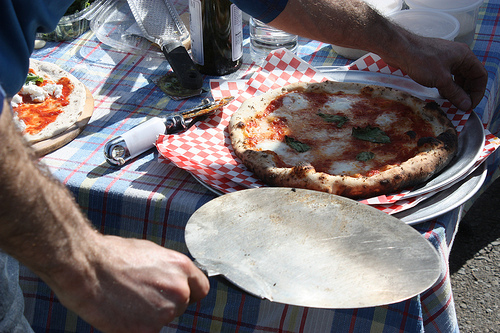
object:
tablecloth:
[6, 2, 495, 331]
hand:
[52, 232, 214, 331]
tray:
[182, 184, 445, 309]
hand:
[403, 34, 490, 112]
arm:
[0, 112, 99, 273]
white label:
[231, 4, 243, 60]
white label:
[190, 0, 202, 62]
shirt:
[1, 2, 286, 127]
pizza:
[10, 57, 88, 154]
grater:
[125, 0, 201, 91]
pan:
[180, 186, 441, 313]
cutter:
[102, 95, 234, 167]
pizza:
[228, 80, 457, 194]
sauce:
[258, 97, 432, 175]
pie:
[223, 78, 454, 195]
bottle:
[192, 1, 243, 76]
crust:
[228, 79, 456, 194]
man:
[0, 0, 491, 333]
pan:
[223, 76, 459, 191]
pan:
[381, 157, 486, 222]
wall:
[437, 230, 500, 333]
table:
[28, 3, 500, 276]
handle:
[102, 114, 171, 166]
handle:
[192, 261, 215, 275]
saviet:
[155, 46, 320, 189]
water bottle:
[247, 16, 298, 66]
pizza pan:
[179, 69, 486, 199]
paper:
[152, 47, 500, 212]